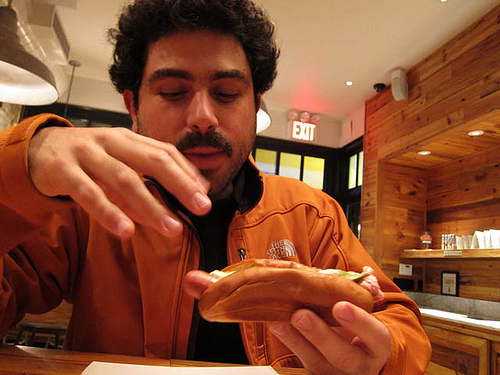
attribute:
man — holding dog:
[0, 20, 312, 298]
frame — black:
[425, 258, 465, 297]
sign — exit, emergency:
[285, 109, 329, 137]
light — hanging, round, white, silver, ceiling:
[249, 81, 284, 133]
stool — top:
[16, 287, 99, 352]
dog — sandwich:
[169, 247, 360, 326]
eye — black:
[201, 51, 259, 106]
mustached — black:
[169, 121, 251, 146]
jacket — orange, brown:
[61, 164, 369, 355]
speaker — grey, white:
[376, 54, 417, 105]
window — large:
[254, 132, 341, 186]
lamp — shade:
[0, 42, 42, 97]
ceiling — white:
[324, 19, 377, 77]